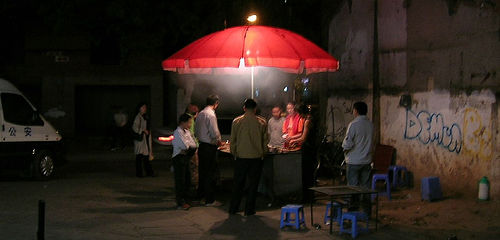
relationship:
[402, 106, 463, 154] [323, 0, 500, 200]
graffiti on wall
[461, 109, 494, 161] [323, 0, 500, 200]
graffiti on wall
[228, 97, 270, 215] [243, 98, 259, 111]
man showing head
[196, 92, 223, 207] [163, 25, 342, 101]
person standing under umbrella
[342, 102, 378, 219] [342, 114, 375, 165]
man with jacket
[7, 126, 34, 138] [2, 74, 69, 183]
asian charaacter on van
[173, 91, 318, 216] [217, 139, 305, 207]
people next to cart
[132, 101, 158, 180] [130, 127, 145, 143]
woman carrying black purse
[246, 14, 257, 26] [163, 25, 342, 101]
lamp on top of umbrella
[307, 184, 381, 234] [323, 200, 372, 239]
table over stools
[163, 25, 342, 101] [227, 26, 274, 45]
umbrella with light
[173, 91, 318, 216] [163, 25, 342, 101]
people standing under umbrella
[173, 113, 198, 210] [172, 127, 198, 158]
man wearing shirt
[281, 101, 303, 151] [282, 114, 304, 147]
person wearing orange shirt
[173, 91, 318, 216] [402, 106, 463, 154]
people next to graffiti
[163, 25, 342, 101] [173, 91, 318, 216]
umbrella above people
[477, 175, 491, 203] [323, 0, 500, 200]
jag next to wall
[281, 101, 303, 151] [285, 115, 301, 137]
person wearing scarf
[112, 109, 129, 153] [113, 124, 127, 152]
lady wearing pants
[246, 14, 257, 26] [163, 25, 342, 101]
light above umbrella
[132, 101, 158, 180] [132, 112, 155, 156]
lady wearing coat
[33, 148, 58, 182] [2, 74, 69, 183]
front tire on van